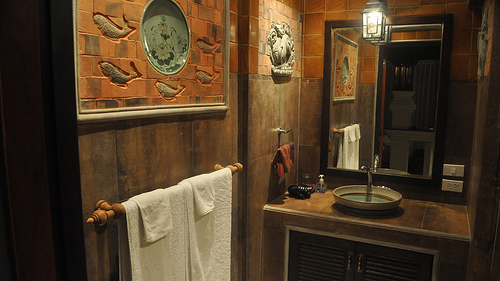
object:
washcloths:
[117, 168, 232, 281]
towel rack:
[88, 162, 244, 226]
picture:
[72, 2, 230, 123]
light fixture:
[359, 0, 393, 45]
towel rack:
[275, 127, 296, 151]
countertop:
[255, 184, 472, 238]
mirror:
[320, 15, 451, 182]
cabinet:
[260, 183, 472, 281]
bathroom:
[2, 2, 499, 280]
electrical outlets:
[442, 179, 463, 193]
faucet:
[360, 166, 373, 203]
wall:
[3, 0, 262, 281]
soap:
[313, 175, 328, 193]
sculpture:
[266, 23, 296, 76]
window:
[376, 40, 441, 186]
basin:
[333, 185, 403, 219]